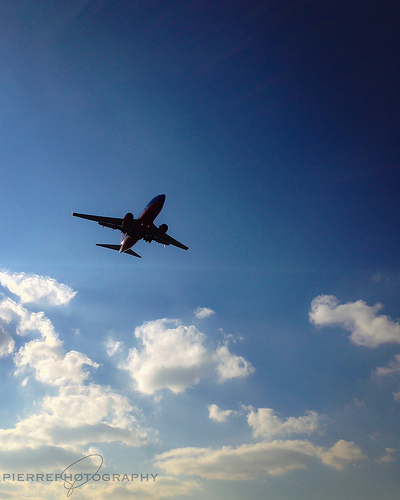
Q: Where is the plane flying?
A: In the sky.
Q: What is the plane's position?
A: In the midst of clouds.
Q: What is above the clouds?
A: Dark blue patch sky.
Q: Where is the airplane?
A: Up high in the sky.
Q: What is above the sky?
A: A blue sky with clouds.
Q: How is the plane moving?
A: Its ascending into the sky.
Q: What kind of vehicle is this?
A: Airplane.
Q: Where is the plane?
A: Sky.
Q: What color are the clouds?
A: White.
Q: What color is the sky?
A: Blue.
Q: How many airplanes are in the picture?
A: One.